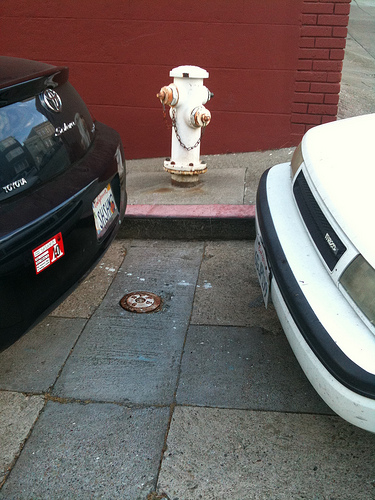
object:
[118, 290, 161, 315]
hole cover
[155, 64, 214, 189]
hydrant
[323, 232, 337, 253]
mazda trademark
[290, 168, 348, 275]
grill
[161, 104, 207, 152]
chain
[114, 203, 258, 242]
curb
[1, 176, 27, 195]
mark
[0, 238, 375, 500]
road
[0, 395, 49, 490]
cracks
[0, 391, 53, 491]
weeds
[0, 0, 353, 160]
wall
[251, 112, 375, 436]
cars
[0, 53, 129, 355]
cars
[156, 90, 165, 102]
cap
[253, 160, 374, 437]
bumper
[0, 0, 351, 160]
building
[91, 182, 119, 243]
license plate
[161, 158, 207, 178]
base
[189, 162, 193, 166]
screw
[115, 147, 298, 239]
sidewalk